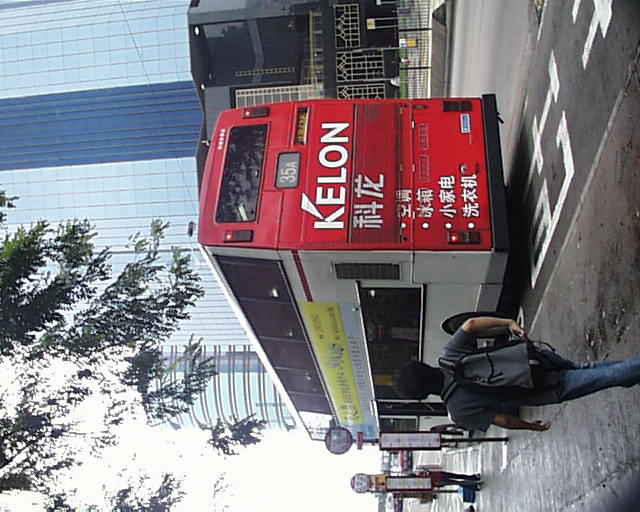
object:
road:
[461, 0, 640, 259]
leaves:
[0, 221, 81, 360]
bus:
[194, 91, 514, 452]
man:
[392, 317, 640, 434]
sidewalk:
[398, 399, 640, 512]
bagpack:
[448, 341, 556, 403]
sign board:
[325, 426, 445, 494]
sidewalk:
[433, 0, 640, 510]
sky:
[0, 343, 389, 512]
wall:
[0, 154, 213, 254]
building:
[0, 0, 415, 431]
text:
[300, 121, 350, 230]